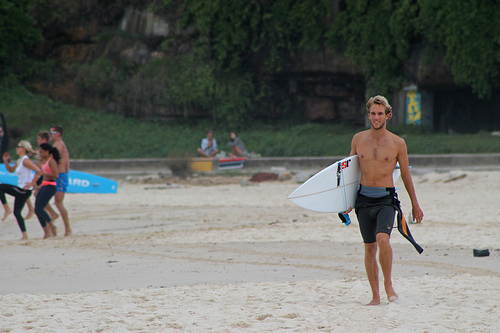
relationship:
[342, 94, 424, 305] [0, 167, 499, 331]
man on beach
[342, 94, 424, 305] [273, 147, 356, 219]
man on surfboard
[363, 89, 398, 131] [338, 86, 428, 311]
hair on man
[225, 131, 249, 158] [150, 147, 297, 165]
people sitting in area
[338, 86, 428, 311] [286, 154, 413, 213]
man carrying board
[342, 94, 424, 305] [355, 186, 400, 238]
man wearing wetsuit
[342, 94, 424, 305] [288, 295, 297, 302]
man in sand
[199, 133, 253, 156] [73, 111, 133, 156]
people sitting on grass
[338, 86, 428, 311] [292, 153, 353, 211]
man carrying surfboard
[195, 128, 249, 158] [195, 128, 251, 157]
people sitting on grass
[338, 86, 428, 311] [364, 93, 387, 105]
man has hair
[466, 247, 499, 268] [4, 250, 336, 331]
garbage on beach